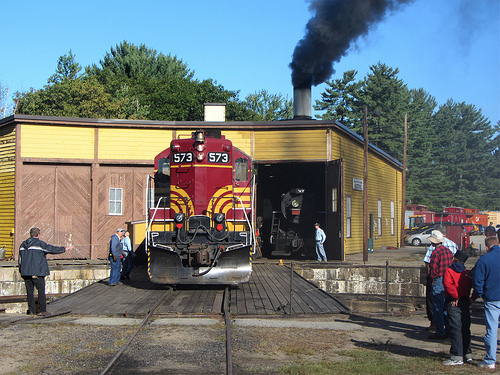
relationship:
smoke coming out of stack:
[290, 1, 408, 91] [289, 82, 316, 118]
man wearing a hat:
[416, 225, 454, 342] [421, 227, 450, 245]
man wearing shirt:
[426, 229, 455, 340] [424, 240, 458, 284]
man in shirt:
[473, 236, 499, 367] [474, 243, 481, 282]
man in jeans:
[473, 236, 499, 367] [467, 297, 480, 316]